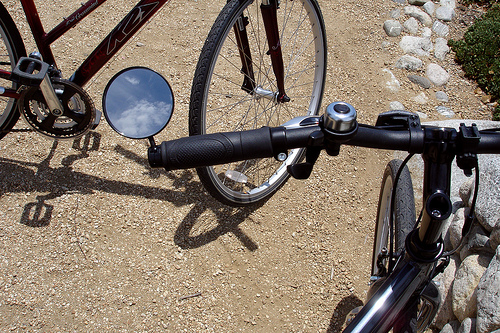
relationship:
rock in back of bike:
[383, 36, 430, 73] [2, 0, 497, 327]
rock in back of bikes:
[379, 0, 497, 110] [1, 3, 496, 328]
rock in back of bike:
[373, 0, 480, 107] [147, 97, 498, 329]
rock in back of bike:
[373, 0, 480, 107] [6, 4, 329, 209]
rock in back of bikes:
[46, 254, 73, 278] [1, 3, 496, 328]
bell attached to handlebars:
[321, 94, 371, 148] [141, 125, 366, 171]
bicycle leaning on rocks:
[102, 66, 499, 333] [410, 118, 499, 331]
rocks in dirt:
[378, 4, 470, 112] [4, 3, 482, 331]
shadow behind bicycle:
[4, 130, 260, 252] [0, 0, 327, 209]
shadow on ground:
[4, 130, 260, 252] [18, 160, 276, 311]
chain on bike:
[1, 77, 95, 137] [6, 4, 329, 209]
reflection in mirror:
[102, 67, 172, 137] [101, 67, 175, 142]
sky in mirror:
[105, 69, 175, 142] [101, 67, 175, 142]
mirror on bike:
[101, 67, 175, 142] [101, 65, 498, 332]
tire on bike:
[184, 0, 326, 209] [6, 4, 329, 209]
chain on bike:
[9, 80, 98, 139] [6, 4, 329, 209]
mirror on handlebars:
[92, 63, 179, 143] [135, 98, 497, 172]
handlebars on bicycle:
[135, 98, 497, 172] [96, 57, 498, 329]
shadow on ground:
[4, 130, 260, 252] [2, 0, 499, 332]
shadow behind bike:
[4, 130, 260, 252] [6, 4, 329, 209]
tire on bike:
[186, 0, 332, 208] [6, 4, 329, 209]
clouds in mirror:
[113, 74, 169, 131] [101, 67, 175, 142]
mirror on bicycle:
[101, 67, 175, 142] [102, 66, 484, 323]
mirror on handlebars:
[101, 67, 175, 142] [146, 100, 500, 172]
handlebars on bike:
[146, 100, 500, 172] [321, 159, 499, 331]